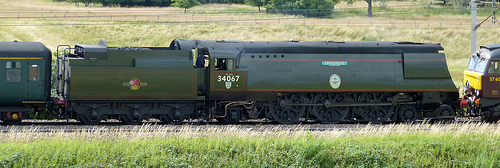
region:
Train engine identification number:
[215, 71, 242, 84]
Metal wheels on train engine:
[268, 91, 458, 124]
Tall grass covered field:
[7, 130, 494, 164]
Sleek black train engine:
[189, 36, 465, 129]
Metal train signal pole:
[466, 5, 483, 59]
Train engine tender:
[51, 38, 204, 122]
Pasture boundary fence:
[6, 6, 322, 26]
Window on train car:
[3, 57, 25, 85]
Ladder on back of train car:
[54, 43, 72, 100]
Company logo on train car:
[116, 75, 151, 92]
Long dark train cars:
[1, 36, 457, 121]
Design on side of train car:
[315, 55, 350, 80]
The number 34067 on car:
[210, 65, 250, 85]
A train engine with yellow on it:
[455, 40, 495, 120]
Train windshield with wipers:
[461, 50, 486, 70]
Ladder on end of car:
[46, 37, 71, 102]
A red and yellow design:
[115, 66, 145, 91]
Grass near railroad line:
[15, 131, 326, 166]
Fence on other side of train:
[5, 5, 420, 27]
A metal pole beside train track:
[467, 5, 484, 50]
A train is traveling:
[0, 39, 498, 124]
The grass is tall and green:
[1, 134, 498, 166]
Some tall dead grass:
[1, 119, 498, 133]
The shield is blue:
[224, 81, 231, 88]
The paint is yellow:
[464, 69, 482, 90]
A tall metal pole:
[470, 1, 477, 53]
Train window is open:
[6, 59, 21, 79]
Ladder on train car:
[56, 44, 69, 99]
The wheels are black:
[267, 92, 454, 125]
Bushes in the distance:
[267, 0, 333, 19]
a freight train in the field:
[1, 3, 496, 165]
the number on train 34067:
[205, 60, 248, 92]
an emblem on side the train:
[114, 75, 155, 94]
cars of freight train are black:
[8, 19, 466, 129]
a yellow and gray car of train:
[459, 40, 498, 120]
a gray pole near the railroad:
[451, 0, 498, 125]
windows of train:
[0, 55, 47, 89]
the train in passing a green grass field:
[8, 45, 485, 165]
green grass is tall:
[6, 107, 495, 165]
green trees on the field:
[89, 0, 409, 28]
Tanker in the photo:
[83, 51, 169, 91]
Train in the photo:
[130, 34, 493, 113]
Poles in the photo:
[448, 12, 486, 35]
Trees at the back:
[284, 2, 358, 21]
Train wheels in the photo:
[212, 91, 379, 121]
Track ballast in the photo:
[245, 119, 357, 136]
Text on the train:
[214, 69, 243, 93]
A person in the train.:
[209, 56, 230, 72]